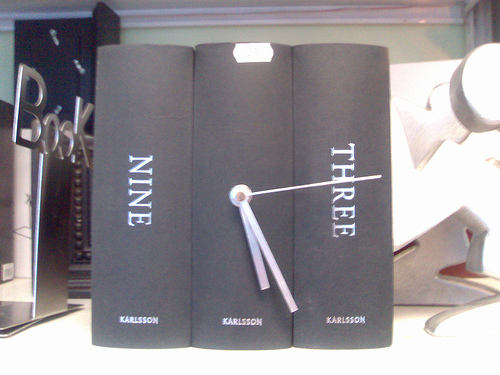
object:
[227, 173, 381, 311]
time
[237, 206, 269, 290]
hands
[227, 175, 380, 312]
clack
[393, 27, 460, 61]
wall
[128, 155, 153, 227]
nine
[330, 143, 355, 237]
three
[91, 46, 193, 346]
book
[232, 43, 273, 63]
light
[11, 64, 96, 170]
frame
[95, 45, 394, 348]
face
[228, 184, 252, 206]
center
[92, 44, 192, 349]
metal book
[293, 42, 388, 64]
end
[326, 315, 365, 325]
brand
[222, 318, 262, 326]
metal tag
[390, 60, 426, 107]
white trim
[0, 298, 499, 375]
shelf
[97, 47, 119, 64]
dark spot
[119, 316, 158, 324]
black beads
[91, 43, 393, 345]
black clock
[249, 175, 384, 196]
second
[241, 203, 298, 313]
hand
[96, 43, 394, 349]
stack of books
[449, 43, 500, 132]
silver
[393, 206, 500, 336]
stand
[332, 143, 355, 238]
inlaid